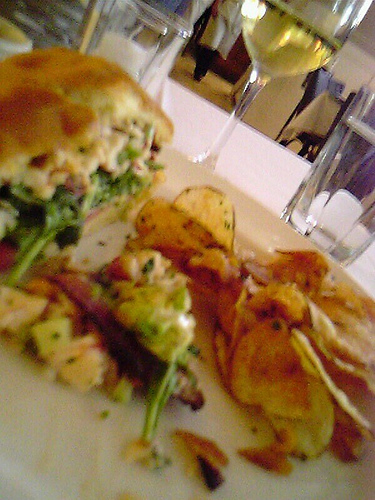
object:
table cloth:
[164, 75, 375, 303]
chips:
[170, 183, 374, 461]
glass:
[75, 0, 195, 98]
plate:
[0, 145, 375, 500]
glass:
[278, 84, 375, 268]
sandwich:
[1, 48, 208, 446]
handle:
[190, 67, 268, 174]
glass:
[191, 0, 375, 176]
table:
[0, 75, 375, 500]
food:
[0, 0, 375, 500]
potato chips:
[124, 183, 375, 500]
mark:
[271, 318, 283, 332]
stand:
[191, 62, 276, 174]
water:
[292, 117, 374, 264]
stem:
[200, 60, 273, 169]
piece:
[167, 424, 231, 496]